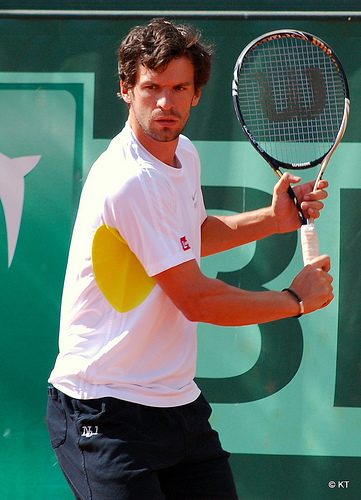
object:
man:
[46, 11, 333, 497]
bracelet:
[281, 285, 308, 324]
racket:
[229, 23, 351, 278]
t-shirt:
[45, 123, 208, 410]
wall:
[0, 3, 360, 499]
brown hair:
[116, 17, 215, 89]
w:
[255, 57, 327, 126]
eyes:
[169, 81, 187, 94]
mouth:
[151, 115, 180, 129]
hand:
[271, 170, 331, 234]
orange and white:
[290, 27, 350, 180]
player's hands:
[291, 260, 334, 317]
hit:
[231, 29, 350, 181]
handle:
[296, 220, 320, 272]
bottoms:
[39, 383, 158, 498]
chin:
[135, 107, 191, 147]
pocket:
[70, 400, 109, 440]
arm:
[109, 170, 302, 327]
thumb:
[272, 169, 302, 197]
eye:
[137, 81, 162, 95]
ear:
[117, 74, 133, 106]